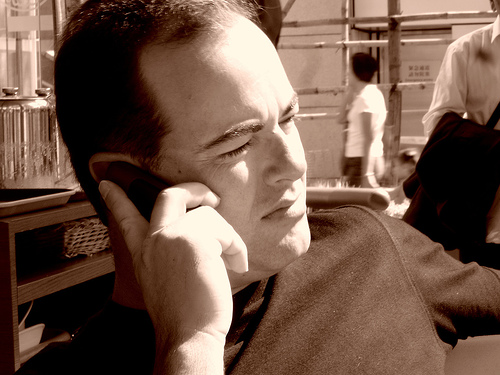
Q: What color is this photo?
A: Black and white.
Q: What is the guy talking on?
A: A cell phone.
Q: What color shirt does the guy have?
A: Black.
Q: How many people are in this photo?
A: Three.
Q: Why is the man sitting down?
A: To talk on the phone.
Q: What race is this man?
A: White.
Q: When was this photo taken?
A: Daytime.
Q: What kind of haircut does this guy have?
A: Short.